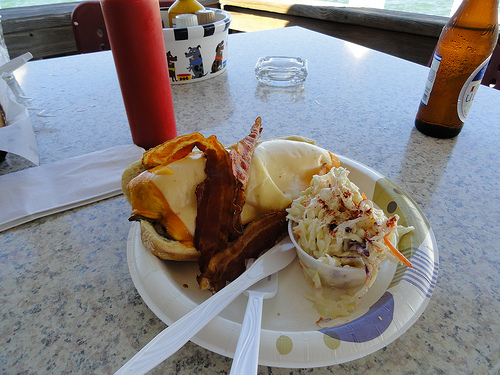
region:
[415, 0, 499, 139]
a bottle of beer sitting on the table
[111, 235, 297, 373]
a white plastic knife and fork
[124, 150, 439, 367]
a white paper plate full of food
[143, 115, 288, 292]
three strips of crispy bacon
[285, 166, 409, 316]
a cup full of cole slaw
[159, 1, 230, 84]
a white bowl full of condiments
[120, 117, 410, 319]
a large sandwich and a serving of cole slaw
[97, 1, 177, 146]
a tall red bottle of ketchup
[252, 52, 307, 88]
a glass ashtray sitting on the table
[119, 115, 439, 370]
a plate of food sitting on the table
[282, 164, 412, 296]
coleslaw in a cup.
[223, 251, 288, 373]
White plastic fork on plate.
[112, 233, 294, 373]
White plastic knife on the plate.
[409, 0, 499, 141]
Bottle on the table.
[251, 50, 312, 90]
clear ashtray on the table.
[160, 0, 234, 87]
bowl on the table.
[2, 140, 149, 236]
White napkin on the table.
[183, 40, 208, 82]
dog on the bowl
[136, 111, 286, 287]
Bacon on the sandwich.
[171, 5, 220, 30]
Salt and pepper shakers in bowl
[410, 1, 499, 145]
Beer bottle sitting on table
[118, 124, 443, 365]
Plate with lots of food on it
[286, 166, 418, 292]
Plastic cup of coleslaw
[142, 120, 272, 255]
Strips of bacon on plate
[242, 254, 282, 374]
Plastic fork on plate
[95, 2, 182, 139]
Squeeze bottle of ketchup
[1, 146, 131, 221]
White paper napkin on table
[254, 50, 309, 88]
Glass ashtray on top of table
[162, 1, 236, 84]
Bowl with dog design on side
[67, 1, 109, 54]
Maroon chair by table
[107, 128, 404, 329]
food on the plate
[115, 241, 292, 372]
a white knife and fork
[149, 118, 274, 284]
pieces of bacon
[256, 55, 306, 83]
an ash tray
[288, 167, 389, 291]
a cup of coleslaw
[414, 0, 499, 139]
a bottle of beer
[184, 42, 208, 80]
a dog on the dish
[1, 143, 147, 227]
a white folded napkin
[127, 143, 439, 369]
a paper plate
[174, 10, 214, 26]
salt and pepper shakers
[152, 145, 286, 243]
cheese on the burger